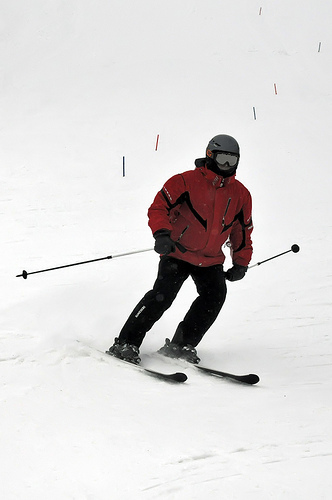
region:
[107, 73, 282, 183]
Red and blue sticks in the snow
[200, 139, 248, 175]
Black and red goggles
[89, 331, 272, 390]
The skis are black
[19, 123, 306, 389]
The skier is holding ski poles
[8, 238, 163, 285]
Black and white ski pole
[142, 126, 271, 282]
The skier is wearing a red jacket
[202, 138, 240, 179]
The skier is wearing a black helmet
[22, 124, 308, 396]
The skier is skiing down a hill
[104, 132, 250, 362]
The skier is wearing black pants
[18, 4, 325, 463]
The hill is covered in snow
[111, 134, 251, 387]
person skiing in white snow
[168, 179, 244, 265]
person wearing red jacket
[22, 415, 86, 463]
hill side covered in white snow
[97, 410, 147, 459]
hill side covered in white snow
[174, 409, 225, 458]
hill side covered in white snow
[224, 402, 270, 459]
hill side covered in white snow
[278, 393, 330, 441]
hill side covered in white snow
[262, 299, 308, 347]
hill side covered in white snow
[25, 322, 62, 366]
hill side covered in white snow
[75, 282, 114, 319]
hill side covered in white snow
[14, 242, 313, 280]
A PAIR OF SKI POLES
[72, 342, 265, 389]
A PAIR OF SKIS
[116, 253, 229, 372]
A PAIR OF BLACK SNOW PANTS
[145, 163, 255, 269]
A RED SKI JACKET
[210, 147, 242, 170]
A PAIR OF SKI GOGGLES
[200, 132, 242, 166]
A SKI HELMET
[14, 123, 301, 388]
A PERSON SKIING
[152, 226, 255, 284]
A PAIR OF BLACK GLOVES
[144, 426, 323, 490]
TRACKS IN THE SNOW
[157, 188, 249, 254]
BLACK MARKINGS ON A RED JACKET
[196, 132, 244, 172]
Person wearing gray helmet.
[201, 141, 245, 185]
Person wearing ski goggles on face.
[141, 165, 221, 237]
Person wearing red and black coat.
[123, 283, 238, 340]
Person wearing black pants.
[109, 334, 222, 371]
Person wearing dark boots.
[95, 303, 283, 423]
2 skis on person's feet.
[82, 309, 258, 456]
Person skiing on snow.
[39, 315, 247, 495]
Ground is covered in snow.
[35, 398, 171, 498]
Snow on ground is white in color.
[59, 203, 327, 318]
Person holding 2 ski poles.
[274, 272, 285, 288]
part of the snow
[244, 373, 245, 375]
part of a board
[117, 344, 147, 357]
part of a skate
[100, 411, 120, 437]
tip of the snow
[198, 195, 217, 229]
part of a jacket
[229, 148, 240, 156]
part of an helmet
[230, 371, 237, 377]
edge of a board